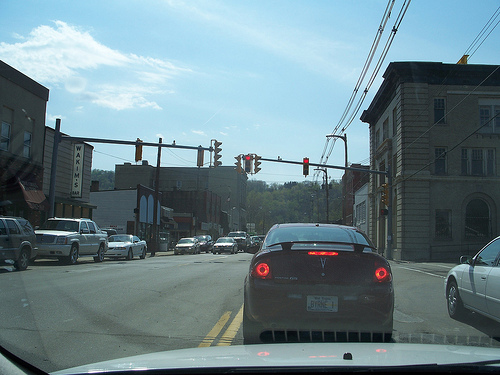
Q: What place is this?
A: It is a street.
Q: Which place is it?
A: It is a street.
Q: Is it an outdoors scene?
A: Yes, it is outdoors.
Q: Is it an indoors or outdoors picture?
A: It is outdoors.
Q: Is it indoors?
A: No, it is outdoors.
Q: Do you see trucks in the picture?
A: Yes, there is a truck.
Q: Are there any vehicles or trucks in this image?
A: Yes, there is a truck.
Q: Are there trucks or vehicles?
A: Yes, there is a truck.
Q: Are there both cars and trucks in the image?
A: Yes, there are both a truck and a car.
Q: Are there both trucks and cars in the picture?
A: Yes, there are both a truck and a car.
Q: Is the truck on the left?
A: Yes, the truck is on the left of the image.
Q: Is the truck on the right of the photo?
A: No, the truck is on the left of the image.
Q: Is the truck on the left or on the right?
A: The truck is on the left of the image.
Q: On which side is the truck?
A: The truck is on the left of the image.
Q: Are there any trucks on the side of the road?
A: Yes, there is a truck on the side of the road.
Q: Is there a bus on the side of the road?
A: No, there is a truck on the side of the road.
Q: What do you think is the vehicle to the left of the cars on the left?
A: The vehicle is a truck.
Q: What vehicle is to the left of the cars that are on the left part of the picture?
A: The vehicle is a truck.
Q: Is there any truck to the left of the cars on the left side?
A: Yes, there is a truck to the left of the cars.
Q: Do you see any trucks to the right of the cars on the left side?
A: No, the truck is to the left of the cars.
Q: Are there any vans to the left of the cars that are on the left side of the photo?
A: No, there is a truck to the left of the cars.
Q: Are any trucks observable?
A: Yes, there is a truck.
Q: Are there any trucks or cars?
A: Yes, there is a truck.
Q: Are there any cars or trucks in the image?
A: Yes, there is a truck.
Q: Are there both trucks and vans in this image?
A: No, there is a truck but no vans.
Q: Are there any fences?
A: No, there are no fences.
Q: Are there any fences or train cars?
A: No, there are no fences or train cars.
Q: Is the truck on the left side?
A: Yes, the truck is on the left of the image.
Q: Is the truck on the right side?
A: No, the truck is on the left of the image.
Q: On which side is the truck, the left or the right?
A: The truck is on the left of the image.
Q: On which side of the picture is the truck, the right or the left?
A: The truck is on the left of the image.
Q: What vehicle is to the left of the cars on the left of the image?
A: The vehicle is a truck.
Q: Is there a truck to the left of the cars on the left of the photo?
A: Yes, there is a truck to the left of the cars.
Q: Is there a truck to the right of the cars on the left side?
A: No, the truck is to the left of the cars.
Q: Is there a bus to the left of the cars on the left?
A: No, there is a truck to the left of the cars.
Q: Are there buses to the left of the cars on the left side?
A: No, there is a truck to the left of the cars.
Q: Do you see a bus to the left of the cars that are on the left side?
A: No, there is a truck to the left of the cars.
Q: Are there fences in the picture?
A: No, there are no fences.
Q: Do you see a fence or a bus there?
A: No, there are no fences or buses.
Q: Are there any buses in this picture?
A: No, there are no buses.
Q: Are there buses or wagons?
A: No, there are no buses or wagons.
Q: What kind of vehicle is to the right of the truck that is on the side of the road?
A: The vehicles are cars.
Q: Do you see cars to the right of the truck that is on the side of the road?
A: Yes, there are cars to the right of the truck.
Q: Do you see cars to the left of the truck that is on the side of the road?
A: No, the cars are to the right of the truck.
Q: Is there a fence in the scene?
A: No, there are no fences.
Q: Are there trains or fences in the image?
A: No, there are no fences or trains.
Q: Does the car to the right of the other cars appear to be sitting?
A: Yes, the car is sitting.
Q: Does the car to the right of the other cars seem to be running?
A: No, the car is sitting.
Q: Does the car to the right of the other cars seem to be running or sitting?
A: The car is sitting.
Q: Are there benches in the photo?
A: No, there are no benches.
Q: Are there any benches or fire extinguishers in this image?
A: No, there are no benches or fire extinguishers.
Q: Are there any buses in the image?
A: No, there are no buses.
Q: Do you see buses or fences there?
A: No, there are no buses or fences.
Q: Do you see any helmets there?
A: No, there are no helmets.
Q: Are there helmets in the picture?
A: No, there are no helmets.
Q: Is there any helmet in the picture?
A: No, there are no helmets.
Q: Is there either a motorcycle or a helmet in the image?
A: No, there are no helmets or motorcycles.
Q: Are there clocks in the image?
A: No, there are no clocks.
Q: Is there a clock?
A: No, there are no clocks.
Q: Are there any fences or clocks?
A: No, there are no clocks or fences.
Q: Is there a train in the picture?
A: No, there are no trains.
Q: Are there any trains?
A: No, there are no trains.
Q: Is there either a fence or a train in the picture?
A: No, there are no trains or fences.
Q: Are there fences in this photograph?
A: No, there are no fences.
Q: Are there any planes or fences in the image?
A: No, there are no fences or planes.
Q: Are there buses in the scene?
A: No, there are no buses.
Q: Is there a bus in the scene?
A: No, there are no buses.